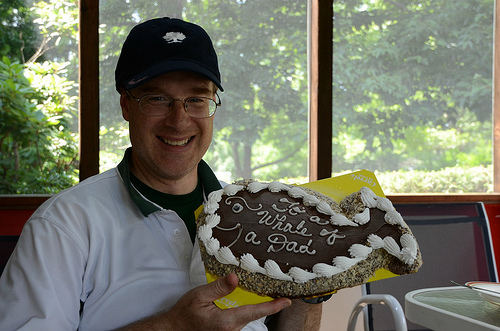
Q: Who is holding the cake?
A: A man.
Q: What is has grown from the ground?
A: Trees.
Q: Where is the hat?
A: On the man's head.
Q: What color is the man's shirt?
A: White.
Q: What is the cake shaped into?
A: A whale.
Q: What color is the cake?
A: Brown and white.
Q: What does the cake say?
A: To a whale of a dad.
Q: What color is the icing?
A: White.